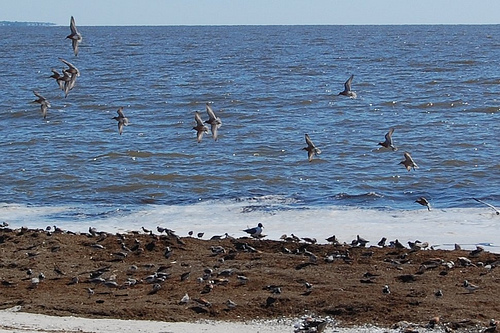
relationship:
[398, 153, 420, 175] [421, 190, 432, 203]
bird with wings open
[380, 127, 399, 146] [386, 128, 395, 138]
bird with wings overhead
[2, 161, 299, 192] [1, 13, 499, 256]
ripples are in water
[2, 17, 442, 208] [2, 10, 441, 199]
group of birds